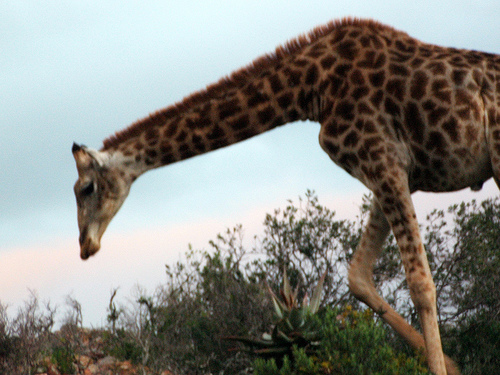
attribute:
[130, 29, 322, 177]
neck — long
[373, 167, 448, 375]
leg — long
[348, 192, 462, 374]
leg — long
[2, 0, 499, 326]
sky — cloudy, blue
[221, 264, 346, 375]
plant — spiked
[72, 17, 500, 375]
giraffe — walking, brown, white, young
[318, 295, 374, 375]
flowers — yellow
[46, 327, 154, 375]
rocks — gray, tan, large, brown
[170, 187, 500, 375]
trees — green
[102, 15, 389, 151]
mane — short, brown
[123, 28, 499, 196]
spots — brown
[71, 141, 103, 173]
ears — perked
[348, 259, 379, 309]
knee — bent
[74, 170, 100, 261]
face — light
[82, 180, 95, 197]
eye — black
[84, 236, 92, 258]
mouth — closed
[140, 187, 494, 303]
leaves — dying